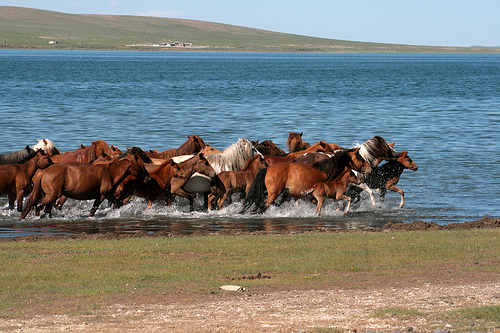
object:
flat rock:
[218, 284, 244, 292]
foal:
[301, 167, 361, 217]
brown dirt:
[223, 265, 277, 294]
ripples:
[56, 78, 161, 130]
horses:
[0, 145, 41, 166]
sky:
[0, 1, 500, 47]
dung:
[224, 273, 272, 280]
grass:
[1, 224, 495, 333]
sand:
[4, 279, 497, 331]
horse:
[206, 155, 268, 212]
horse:
[236, 146, 372, 215]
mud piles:
[3, 216, 499, 236]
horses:
[0, 148, 54, 212]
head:
[364, 135, 399, 162]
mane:
[354, 137, 380, 168]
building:
[151, 41, 193, 48]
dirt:
[2, 285, 496, 330]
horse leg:
[390, 184, 405, 205]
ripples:
[285, 88, 367, 122]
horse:
[321, 136, 399, 208]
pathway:
[0, 213, 499, 333]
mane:
[308, 150, 350, 182]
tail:
[239, 168, 266, 217]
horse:
[294, 152, 329, 165]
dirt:
[0, 215, 498, 242]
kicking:
[0, 181, 405, 225]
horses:
[52, 140, 112, 164]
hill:
[0, 0, 499, 52]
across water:
[0, 46, 499, 217]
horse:
[351, 151, 417, 210]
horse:
[284, 132, 311, 153]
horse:
[17, 156, 140, 220]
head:
[196, 145, 219, 159]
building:
[49, 40, 56, 45]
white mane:
[206, 135, 253, 172]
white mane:
[32, 135, 52, 150]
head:
[30, 148, 49, 168]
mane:
[7, 147, 40, 163]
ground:
[0, 223, 499, 333]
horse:
[172, 138, 263, 177]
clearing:
[2, 34, 499, 53]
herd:
[3, 128, 419, 211]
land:
[0, 220, 499, 329]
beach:
[0, 219, 498, 330]